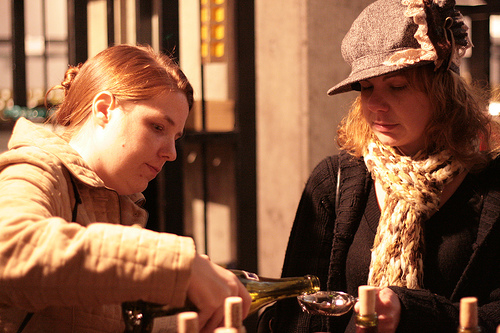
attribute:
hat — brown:
[321, 0, 474, 99]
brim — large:
[325, 52, 420, 96]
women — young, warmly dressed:
[1, 14, 498, 331]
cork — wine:
[456, 294, 478, 329]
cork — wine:
[351, 284, 383, 314]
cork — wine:
[221, 287, 236, 321]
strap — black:
[68, 182, 82, 221]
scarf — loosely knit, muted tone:
[350, 136, 476, 293]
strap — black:
[330, 151, 345, 264]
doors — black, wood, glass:
[1, 0, 256, 270]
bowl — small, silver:
[298, 289, 357, 309]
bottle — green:
[123, 272, 320, 332]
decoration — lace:
[403, 0, 471, 63]